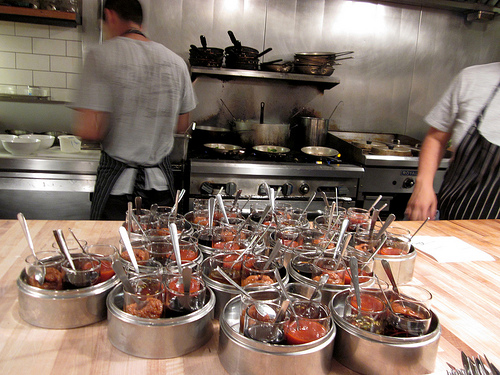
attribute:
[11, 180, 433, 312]
spoons — shiny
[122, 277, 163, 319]
food dish — different, four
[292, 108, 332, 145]
pot — cooking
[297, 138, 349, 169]
skillet — cooking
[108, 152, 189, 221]
apron — tied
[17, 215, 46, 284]
spoon — silver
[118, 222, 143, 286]
spoon — silver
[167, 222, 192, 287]
spoon — silver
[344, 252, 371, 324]
spoon — silver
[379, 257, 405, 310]
spoon — silver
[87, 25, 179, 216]
apron — black, white, striped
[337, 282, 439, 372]
pot — round 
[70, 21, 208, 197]
guy — working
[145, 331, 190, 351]
containers — shiny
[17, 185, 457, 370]
containers — several